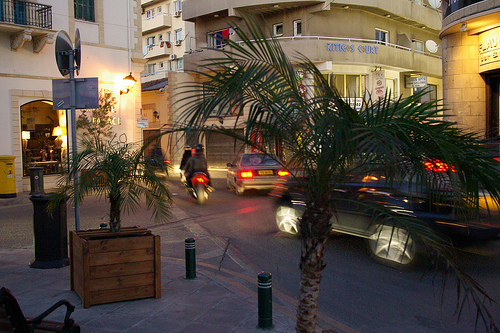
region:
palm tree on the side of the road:
[208, 33, 370, 321]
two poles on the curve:
[172, 230, 285, 320]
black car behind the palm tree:
[251, 155, 478, 270]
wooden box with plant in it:
[65, 120, 170, 302]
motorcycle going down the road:
[172, 125, 217, 200]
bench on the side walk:
[1, 268, 93, 329]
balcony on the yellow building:
[130, 5, 196, 75]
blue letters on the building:
[315, 40, 385, 60]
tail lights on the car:
[235, 160, 290, 185]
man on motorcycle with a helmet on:
[173, 132, 213, 209]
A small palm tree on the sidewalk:
[232, 74, 384, 331]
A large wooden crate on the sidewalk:
[64, 225, 179, 307]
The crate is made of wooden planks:
[71, 230, 163, 302]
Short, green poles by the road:
[180, 238, 204, 275]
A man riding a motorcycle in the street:
[179, 138, 219, 198]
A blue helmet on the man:
[193, 142, 206, 157]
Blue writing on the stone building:
[322, 40, 389, 62]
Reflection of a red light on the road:
[237, 200, 252, 223]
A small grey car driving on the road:
[225, 145, 290, 202]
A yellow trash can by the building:
[0, 150, 27, 200]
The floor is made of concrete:
[111, 297, 242, 329]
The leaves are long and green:
[181, 45, 449, 197]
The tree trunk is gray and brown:
[285, 188, 334, 332]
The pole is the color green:
[253, 266, 282, 329]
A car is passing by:
[261, 175, 491, 265]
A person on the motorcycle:
[176, 136, 222, 203]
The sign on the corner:
[46, 26, 107, 231]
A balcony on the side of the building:
[0, 0, 72, 55]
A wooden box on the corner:
[68, 217, 179, 308]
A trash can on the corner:
[23, 183, 70, 274]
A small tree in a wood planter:
[56, 133, 170, 309]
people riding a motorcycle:
[183, 142, 213, 203]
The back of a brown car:
[226, 150, 288, 197]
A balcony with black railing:
[1, 2, 57, 54]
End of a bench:
[1, 285, 78, 331]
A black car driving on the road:
[272, 149, 498, 269]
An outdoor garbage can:
[28, 191, 72, 269]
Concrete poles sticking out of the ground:
[182, 235, 280, 330]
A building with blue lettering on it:
[181, 2, 446, 180]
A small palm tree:
[149, 35, 483, 332]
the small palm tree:
[187, 41, 441, 327]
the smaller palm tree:
[63, 118, 166, 224]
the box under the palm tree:
[59, 221, 173, 306]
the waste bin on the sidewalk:
[18, 182, 73, 269]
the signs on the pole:
[36, 23, 109, 230]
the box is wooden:
[66, 226, 169, 293]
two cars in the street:
[218, 148, 498, 297]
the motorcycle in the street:
[159, 133, 217, 203]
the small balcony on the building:
[3, 2, 56, 51]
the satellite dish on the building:
[410, 38, 448, 82]